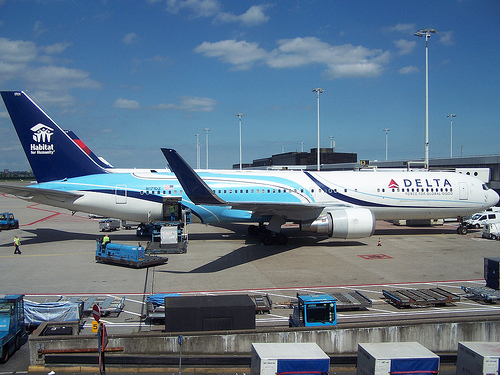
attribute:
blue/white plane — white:
[3, 90, 498, 246]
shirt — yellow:
[10, 238, 21, 248]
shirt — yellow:
[101, 237, 110, 246]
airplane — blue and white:
[4, 79, 496, 284]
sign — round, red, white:
[87, 303, 102, 326]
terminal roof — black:
[248, 147, 365, 167]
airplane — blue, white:
[6, 87, 495, 258]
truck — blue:
[285, 290, 354, 337]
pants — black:
[13, 241, 23, 253]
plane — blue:
[9, 69, 480, 278]